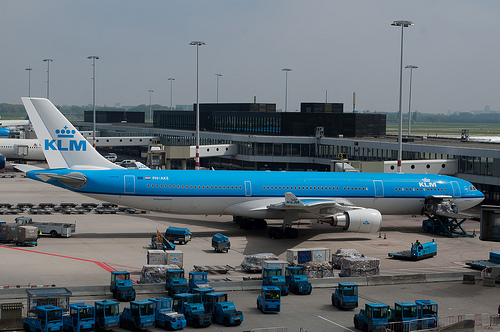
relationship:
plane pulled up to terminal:
[13, 95, 485, 240] [0, 102, 498, 207]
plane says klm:
[13, 95, 485, 240] [44, 138, 88, 154]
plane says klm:
[13, 95, 485, 240] [417, 181, 440, 189]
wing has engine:
[223, 196, 383, 235] [328, 209, 382, 232]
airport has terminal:
[1, 103, 499, 331] [0, 102, 498, 207]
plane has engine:
[13, 95, 485, 240] [328, 209, 382, 232]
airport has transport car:
[1, 103, 499, 331] [94, 299, 124, 331]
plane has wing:
[13, 95, 485, 240] [31, 172, 90, 189]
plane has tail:
[13, 95, 485, 240] [13, 96, 129, 207]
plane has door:
[13, 95, 485, 240] [372, 178, 389, 198]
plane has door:
[13, 95, 485, 240] [122, 172, 139, 193]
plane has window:
[13, 95, 485, 240] [145, 181, 152, 191]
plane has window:
[13, 95, 485, 240] [262, 184, 270, 192]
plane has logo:
[13, 95, 485, 240] [43, 123, 88, 153]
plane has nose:
[13, 95, 485, 240] [459, 179, 485, 212]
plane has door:
[13, 95, 485, 240] [451, 180, 465, 197]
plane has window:
[13, 95, 485, 240] [395, 187, 400, 194]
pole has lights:
[398, 25, 406, 174] [391, 18, 414, 29]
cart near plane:
[165, 225, 198, 246] [13, 95, 485, 240]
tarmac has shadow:
[1, 166, 499, 331] [69, 229, 275, 241]